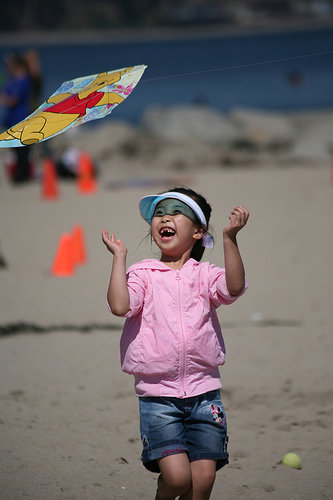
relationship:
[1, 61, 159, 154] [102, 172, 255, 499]
kite above girl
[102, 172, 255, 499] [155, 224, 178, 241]
girl missing front teeth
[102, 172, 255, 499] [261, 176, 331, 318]
girl playing on sand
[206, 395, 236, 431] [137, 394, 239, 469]
character on side of shorts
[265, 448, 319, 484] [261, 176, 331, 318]
ball laying on top of sand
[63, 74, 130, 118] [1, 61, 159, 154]
character on front of kite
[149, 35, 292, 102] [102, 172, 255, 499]
water behind girl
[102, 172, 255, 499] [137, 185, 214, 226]
girl wearing visor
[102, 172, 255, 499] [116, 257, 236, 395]
girl wearing jacket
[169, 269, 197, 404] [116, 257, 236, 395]
zipper on front of jacket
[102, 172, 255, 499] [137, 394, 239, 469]
girl wearing shorts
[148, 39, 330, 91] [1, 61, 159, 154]
string attached to kite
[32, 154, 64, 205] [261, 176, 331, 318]
cone sitting on top of sand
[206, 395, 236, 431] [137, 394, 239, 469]
character on pocket of shorts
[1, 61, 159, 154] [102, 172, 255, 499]
kite flying above girl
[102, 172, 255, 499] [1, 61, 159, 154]
girl looking at kite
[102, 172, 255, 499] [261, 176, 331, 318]
girl standing on sand